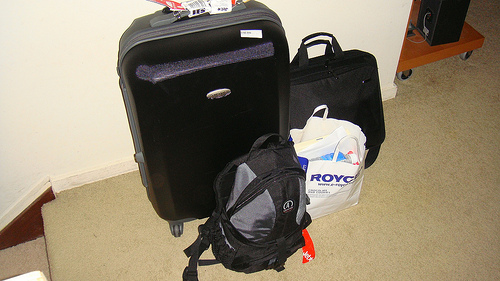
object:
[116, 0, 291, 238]
suitcase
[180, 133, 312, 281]
backpack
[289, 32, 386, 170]
bag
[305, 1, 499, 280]
carpet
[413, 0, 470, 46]
speaker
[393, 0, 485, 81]
cart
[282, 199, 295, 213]
logo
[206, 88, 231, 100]
emblem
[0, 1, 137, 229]
wall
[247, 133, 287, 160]
strap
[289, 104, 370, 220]
bag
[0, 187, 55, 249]
wood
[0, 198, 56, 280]
stair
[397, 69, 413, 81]
wheel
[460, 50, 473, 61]
wheel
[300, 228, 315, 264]
tag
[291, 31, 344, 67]
handle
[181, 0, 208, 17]
tag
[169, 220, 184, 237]
wheel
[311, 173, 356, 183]
letter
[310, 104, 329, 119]
handle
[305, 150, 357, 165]
junk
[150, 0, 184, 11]
tag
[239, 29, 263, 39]
label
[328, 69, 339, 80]
zipper